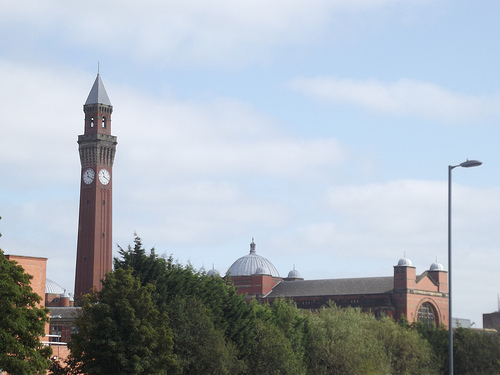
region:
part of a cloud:
[256, 156, 313, 188]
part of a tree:
[155, 302, 229, 360]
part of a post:
[443, 232, 455, 267]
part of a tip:
[91, 44, 100, 81]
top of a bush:
[126, 245, 161, 273]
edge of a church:
[398, 258, 419, 307]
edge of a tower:
[82, 245, 104, 286]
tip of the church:
[241, 230, 258, 252]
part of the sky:
[129, 65, 164, 95]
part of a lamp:
[458, 146, 478, 176]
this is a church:
[72, 76, 119, 284]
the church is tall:
[75, 62, 126, 256]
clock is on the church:
[98, 168, 109, 183]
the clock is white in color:
[99, 168, 114, 186]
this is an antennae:
[95, 50, 105, 73]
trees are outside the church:
[103, 286, 247, 372]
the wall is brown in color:
[82, 201, 110, 261]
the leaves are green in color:
[90, 295, 251, 373]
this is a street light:
[435, 149, 490, 281]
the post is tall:
[435, 152, 489, 354]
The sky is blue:
[0, 1, 499, 330]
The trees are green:
[1, 234, 499, 374]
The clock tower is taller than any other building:
[74, 57, 118, 306]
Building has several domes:
[219, 234, 448, 311]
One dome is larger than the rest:
[202, 234, 304, 279]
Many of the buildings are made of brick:
[1, 254, 451, 374]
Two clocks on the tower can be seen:
[82, 163, 109, 190]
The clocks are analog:
[79, 164, 114, 188]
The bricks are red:
[0, 256, 88, 374]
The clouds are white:
[1, 2, 498, 331]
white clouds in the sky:
[140, 97, 268, 160]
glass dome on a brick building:
[228, 238, 263, 275]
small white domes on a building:
[392, 245, 451, 274]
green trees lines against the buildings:
[128, 270, 337, 367]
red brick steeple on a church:
[81, 60, 120, 292]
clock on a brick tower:
[70, 165, 107, 185]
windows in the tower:
[80, 192, 117, 214]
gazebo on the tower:
[87, 114, 118, 134]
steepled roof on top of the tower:
[67, 73, 119, 102]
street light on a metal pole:
[437, 146, 454, 344]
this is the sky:
[178, 10, 385, 140]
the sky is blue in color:
[373, 27, 465, 64]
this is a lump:
[459, 156, 481, 172]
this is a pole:
[443, 161, 458, 373]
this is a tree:
[83, 289, 158, 372]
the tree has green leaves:
[124, 306, 140, 340]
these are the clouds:
[143, 125, 205, 207]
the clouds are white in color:
[164, 155, 189, 174]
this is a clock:
[100, 168, 110, 185]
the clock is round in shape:
[102, 168, 106, 183]